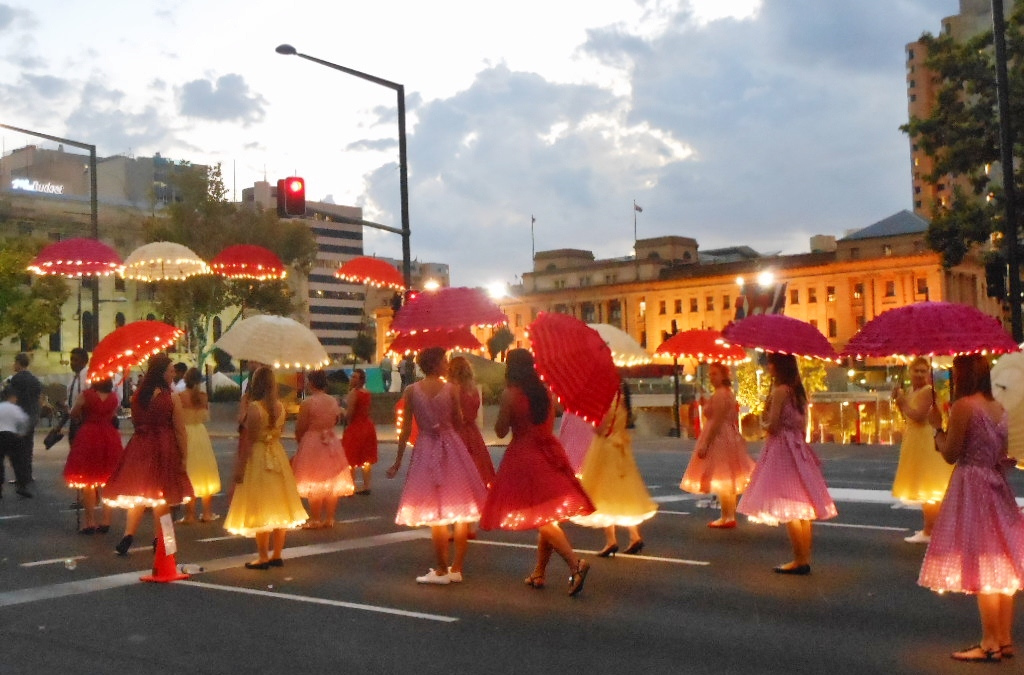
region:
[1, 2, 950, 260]
A blue and white cloudy sky.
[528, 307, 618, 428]
Red umbrella that is angled back the most.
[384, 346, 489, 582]
Brown haired girl in a pink dress with pink umbrella in white shoes.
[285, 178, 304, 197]
Round red traffic light.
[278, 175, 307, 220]
Black traffic light with red illuminated.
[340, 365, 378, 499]
Girl in the brightest red dress with black flats.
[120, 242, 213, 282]
A white umbrella hanging from the air.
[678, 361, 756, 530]
Brown haired girl in a light pink dress with red shoes.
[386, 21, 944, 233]
clouds are dark blue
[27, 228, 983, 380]
umbrellas are white and red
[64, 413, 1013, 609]
dresses all have lights around the bottoms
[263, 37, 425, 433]
light pole for the street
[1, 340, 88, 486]
people are just watching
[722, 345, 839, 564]
woman wearing a pink dress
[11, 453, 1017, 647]
white lines in the street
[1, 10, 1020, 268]
sky is dark with clouds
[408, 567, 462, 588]
shoes are white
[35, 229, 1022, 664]
some people with umbrellas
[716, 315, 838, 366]
the umbrella is pink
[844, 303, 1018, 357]
the umbrella is pink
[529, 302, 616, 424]
the umbrella is pink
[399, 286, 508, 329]
the umbrella is pink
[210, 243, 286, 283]
the umbrella is pink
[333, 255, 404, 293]
the umbrella is pink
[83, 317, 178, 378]
the umbrella is pink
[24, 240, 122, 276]
the umbrella is pink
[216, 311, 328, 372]
the umbrella is white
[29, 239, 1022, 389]
the umbrellas are lit up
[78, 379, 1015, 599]
the dresses are lit up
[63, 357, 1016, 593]
the dresses are red, pink and yellow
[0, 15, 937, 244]
the sky is cloudy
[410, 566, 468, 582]
the girl has white shoes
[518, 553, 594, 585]
the girl has sandals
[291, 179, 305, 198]
the light is red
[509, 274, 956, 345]
the building has many windows